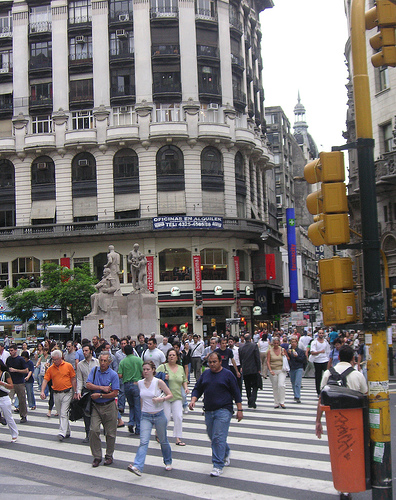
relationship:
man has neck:
[189, 351, 243, 475] [208, 364, 222, 373]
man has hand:
[189, 351, 243, 475] [186, 400, 193, 412]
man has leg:
[189, 351, 243, 475] [211, 410, 233, 476]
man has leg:
[189, 351, 243, 475] [201, 410, 229, 461]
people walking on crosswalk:
[35, 344, 281, 433] [110, 392, 308, 498]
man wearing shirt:
[38, 344, 77, 440] [42, 360, 74, 391]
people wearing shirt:
[152, 348, 190, 447] [153, 360, 191, 402]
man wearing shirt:
[187, 351, 242, 476] [190, 366, 240, 415]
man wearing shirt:
[214, 336, 243, 382] [213, 347, 235, 362]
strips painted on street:
[254, 402, 302, 485] [46, 369, 295, 471]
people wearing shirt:
[125, 355, 173, 478] [133, 376, 164, 411]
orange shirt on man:
[34, 363, 74, 397] [29, 342, 83, 443]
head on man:
[207, 354, 221, 372] [185, 353, 246, 477]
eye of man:
[212, 356, 217, 366] [185, 353, 246, 477]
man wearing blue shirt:
[83, 350, 124, 468] [88, 367, 116, 399]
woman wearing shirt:
[122, 354, 176, 477] [137, 376, 164, 411]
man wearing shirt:
[193, 333, 204, 382] [312, 351, 368, 412]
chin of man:
[214, 362, 217, 368] [189, 351, 243, 475]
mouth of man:
[209, 364, 217, 369] [185, 353, 246, 477]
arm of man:
[84, 372, 113, 392] [83, 350, 124, 468]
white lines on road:
[251, 415, 320, 471] [24, 400, 257, 489]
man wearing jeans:
[189, 351, 243, 475] [204, 407, 230, 463]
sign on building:
[152, 214, 224, 231] [0, 1, 282, 338]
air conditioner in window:
[73, 33, 86, 48] [63, 31, 92, 65]